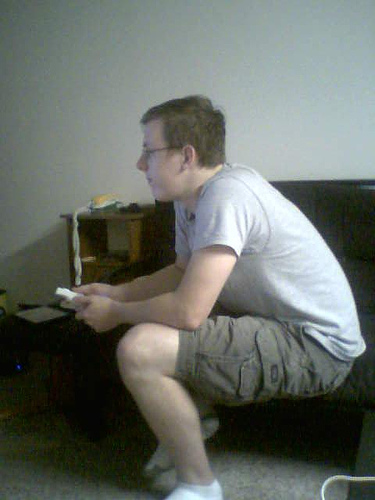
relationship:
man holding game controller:
[64, 93, 369, 497] [54, 280, 97, 314]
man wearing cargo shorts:
[64, 93, 369, 497] [172, 313, 356, 404]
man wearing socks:
[64, 93, 369, 497] [139, 407, 229, 498]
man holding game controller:
[64, 93, 369, 497] [55, 279, 90, 315]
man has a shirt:
[64, 93, 369, 497] [163, 161, 372, 360]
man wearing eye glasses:
[64, 93, 369, 497] [134, 134, 187, 166]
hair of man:
[137, 91, 225, 170] [64, 93, 369, 497]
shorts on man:
[173, 316, 360, 408] [107, 100, 364, 498]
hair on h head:
[137, 91, 225, 170] [134, 99, 230, 205]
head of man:
[134, 99, 230, 205] [64, 93, 369, 497]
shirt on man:
[163, 161, 372, 360] [64, 93, 369, 497]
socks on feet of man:
[178, 479, 222, 500] [64, 93, 369, 497]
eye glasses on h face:
[136, 134, 184, 154] [133, 120, 183, 207]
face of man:
[133, 120, 183, 207] [64, 93, 369, 497]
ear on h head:
[174, 140, 195, 167] [134, 99, 230, 205]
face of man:
[135, 108, 197, 204] [64, 93, 369, 497]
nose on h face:
[134, 152, 150, 168] [135, 108, 197, 204]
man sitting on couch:
[64, 93, 369, 497] [70, 164, 374, 472]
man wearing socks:
[185, 259, 336, 348] [178, 479, 216, 500]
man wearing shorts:
[64, 92, 366, 500] [209, 332, 288, 358]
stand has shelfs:
[85, 203, 138, 245] [74, 250, 132, 273]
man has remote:
[64, 92, 366, 500] [62, 289, 97, 303]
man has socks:
[64, 92, 366, 500] [182, 488, 201, 493]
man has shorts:
[176, 150, 189, 182] [213, 341, 253, 380]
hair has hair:
[137, 91, 225, 170] [181, 108, 198, 140]